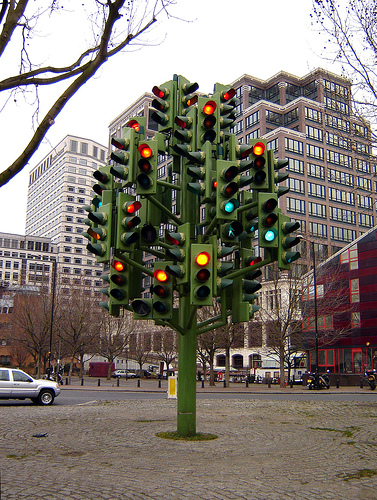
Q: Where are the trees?
A: Across the street.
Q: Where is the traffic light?
A: Center.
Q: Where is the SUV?
A: Left side.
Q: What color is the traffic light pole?
A: Green.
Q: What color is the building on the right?
A: Red.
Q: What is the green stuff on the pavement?
A: Moss.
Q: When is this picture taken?
A: During the day.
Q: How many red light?
A: 15.